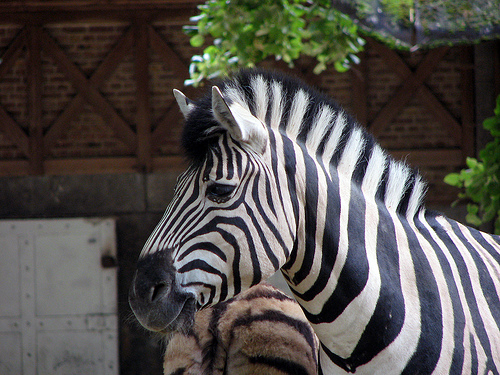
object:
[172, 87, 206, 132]
ear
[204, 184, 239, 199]
eye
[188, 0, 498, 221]
trees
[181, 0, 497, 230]
leaves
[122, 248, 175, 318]
nose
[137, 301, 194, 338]
mouth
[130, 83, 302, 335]
head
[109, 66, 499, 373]
zebra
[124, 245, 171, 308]
black nose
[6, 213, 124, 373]
door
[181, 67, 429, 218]
hair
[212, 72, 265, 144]
ear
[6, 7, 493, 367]
building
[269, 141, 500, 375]
stripe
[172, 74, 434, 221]
mane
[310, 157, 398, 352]
neck